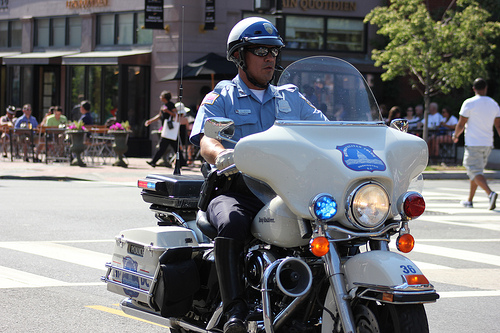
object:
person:
[143, 89, 196, 168]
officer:
[176, 3, 370, 325]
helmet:
[221, 17, 286, 52]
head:
[221, 16, 286, 86]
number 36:
[397, 260, 420, 273]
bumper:
[329, 249, 431, 296]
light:
[347, 181, 393, 228]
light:
[404, 193, 427, 218]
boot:
[211, 232, 251, 331]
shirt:
[456, 94, 500, 148]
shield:
[333, 142, 389, 172]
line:
[0, 241, 109, 272]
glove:
[214, 149, 241, 177]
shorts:
[459, 145, 492, 180]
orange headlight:
[310, 236, 333, 257]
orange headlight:
[396, 233, 416, 252]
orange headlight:
[404, 273, 432, 286]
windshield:
[275, 55, 381, 129]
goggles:
[248, 47, 281, 56]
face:
[248, 44, 277, 81]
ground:
[0, 176, 500, 333]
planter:
[101, 120, 131, 164]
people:
[14, 103, 38, 164]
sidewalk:
[6, 148, 196, 178]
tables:
[6, 125, 34, 162]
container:
[102, 225, 205, 323]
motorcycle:
[92, 46, 432, 330]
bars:
[96, 277, 149, 298]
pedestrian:
[446, 71, 497, 217]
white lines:
[429, 231, 500, 273]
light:
[314, 195, 338, 219]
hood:
[230, 55, 441, 233]